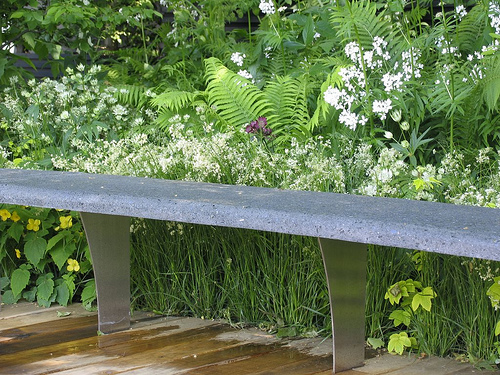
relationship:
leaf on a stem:
[302, 8, 314, 47] [302, 42, 312, 72]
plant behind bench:
[203, 56, 280, 149] [1, 167, 499, 373]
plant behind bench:
[383, 108, 436, 170] [1, 167, 499, 373]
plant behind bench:
[244, 115, 271, 148] [1, 167, 499, 373]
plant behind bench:
[411, 175, 443, 188] [1, 167, 499, 373]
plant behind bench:
[244, 115, 272, 137] [1, 167, 499, 373]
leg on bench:
[80, 212, 133, 334] [1, 167, 499, 373]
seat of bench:
[7, 169, 498, 252] [1, 167, 499, 373]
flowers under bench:
[64, 256, 81, 272] [1, 167, 499, 373]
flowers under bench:
[58, 212, 72, 229] [1, 167, 499, 373]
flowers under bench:
[21, 216, 42, 232] [1, 167, 499, 373]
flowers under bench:
[0, 209, 11, 224] [1, 167, 499, 373]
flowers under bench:
[13, 246, 22, 258] [1, 167, 499, 373]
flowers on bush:
[327, 40, 417, 121] [0, 1, 497, 197]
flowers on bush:
[25, 216, 42, 233] [0, 1, 497, 197]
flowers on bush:
[63, 259, 83, 275] [0, 1, 497, 197]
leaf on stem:
[384, 328, 412, 358] [392, 323, 410, 334]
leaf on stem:
[385, 307, 414, 329] [412, 302, 432, 322]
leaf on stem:
[200, 57, 285, 145] [443, 109, 460, 152]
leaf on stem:
[120, 2, 160, 68] [49, 270, 68, 290]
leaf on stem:
[400, 292, 447, 312] [404, 303, 418, 325]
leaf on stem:
[49, 238, 76, 269] [75, 242, 81, 258]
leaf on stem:
[19, 211, 50, 230] [17, 227, 47, 274]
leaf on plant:
[273, 72, 284, 79] [199, 56, 351, 336]